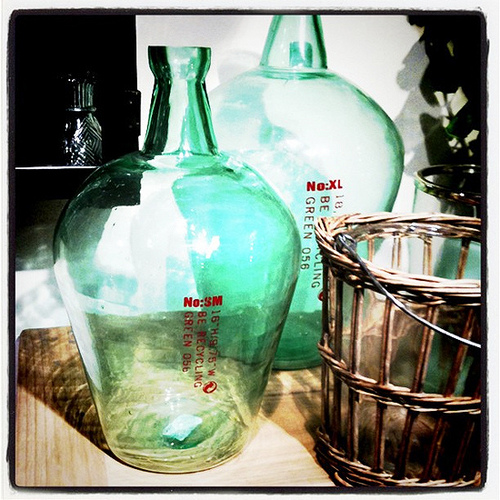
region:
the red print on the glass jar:
[180, 294, 224, 394]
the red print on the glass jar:
[301, 180, 343, 299]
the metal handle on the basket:
[337, 231, 480, 348]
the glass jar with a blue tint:
[52, 44, 299, 471]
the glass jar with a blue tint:
[177, 10, 402, 366]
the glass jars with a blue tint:
[50, 12, 403, 472]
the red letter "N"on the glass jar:
[183, 295, 193, 307]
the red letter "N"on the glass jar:
[306, 180, 316, 191]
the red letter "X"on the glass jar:
[327, 178, 336, 189]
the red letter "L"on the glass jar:
[336, 178, 344, 190]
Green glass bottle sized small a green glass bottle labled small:
[43, 31, 300, 470]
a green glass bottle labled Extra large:
[180, 4, 408, 366]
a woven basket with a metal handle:
[318, 207, 484, 499]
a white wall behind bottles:
[11, 14, 453, 329]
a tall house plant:
[402, 17, 499, 171]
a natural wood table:
[17, 309, 341, 489]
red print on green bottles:
[168, 291, 222, 416]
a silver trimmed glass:
[395, 136, 483, 227]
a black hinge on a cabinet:
[120, 77, 152, 138]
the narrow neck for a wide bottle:
[89, 27, 268, 214]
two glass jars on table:
[46, 54, 405, 471]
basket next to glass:
[326, 238, 476, 493]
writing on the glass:
[167, 293, 237, 409]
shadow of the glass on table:
[1, 314, 115, 456]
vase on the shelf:
[53, 38, 112, 164]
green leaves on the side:
[420, 10, 472, 160]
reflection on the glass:
[84, 150, 241, 267]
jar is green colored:
[144, 59, 279, 471]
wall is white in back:
[334, 14, 401, 106]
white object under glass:
[107, 458, 326, 483]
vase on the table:
[38, 60, 260, 472]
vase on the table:
[243, 15, 375, 215]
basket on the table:
[309, 223, 479, 484]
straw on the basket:
[373, 297, 405, 383]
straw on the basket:
[413, 305, 448, 387]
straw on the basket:
[393, 413, 420, 482]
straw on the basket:
[378, 404, 388, 470]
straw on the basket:
[349, 392, 369, 462]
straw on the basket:
[347, 292, 369, 365]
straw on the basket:
[314, 368, 332, 425]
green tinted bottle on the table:
[56, 45, 288, 477]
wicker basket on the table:
[316, 205, 480, 458]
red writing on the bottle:
[176, 265, 241, 413]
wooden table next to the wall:
[34, 322, 96, 479]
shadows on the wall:
[394, 36, 433, 171]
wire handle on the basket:
[334, 234, 473, 356]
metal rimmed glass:
[416, 160, 473, 208]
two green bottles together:
[137, 26, 310, 288]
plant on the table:
[399, 22, 473, 159]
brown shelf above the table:
[27, 43, 139, 210]